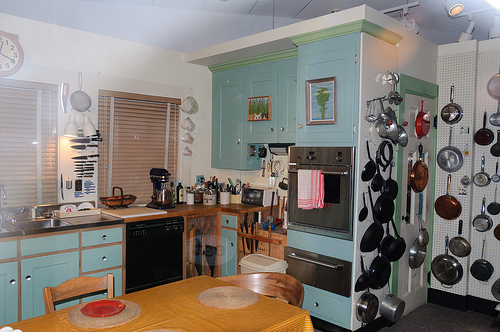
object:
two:
[410, 153, 462, 220]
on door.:
[400, 87, 434, 310]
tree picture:
[310, 82, 333, 121]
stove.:
[287, 146, 354, 236]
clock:
[1, 30, 26, 77]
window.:
[3, 77, 59, 205]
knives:
[70, 144, 100, 152]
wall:
[60, 78, 101, 206]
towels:
[296, 168, 324, 211]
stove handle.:
[289, 168, 348, 178]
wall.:
[8, 14, 212, 207]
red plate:
[80, 299, 127, 316]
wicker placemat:
[66, 300, 145, 326]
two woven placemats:
[70, 287, 267, 330]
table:
[0, 275, 313, 331]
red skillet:
[414, 98, 432, 140]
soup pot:
[380, 287, 406, 323]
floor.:
[378, 302, 499, 331]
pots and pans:
[359, 70, 499, 325]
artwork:
[247, 95, 272, 121]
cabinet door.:
[243, 72, 277, 142]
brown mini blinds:
[98, 92, 181, 196]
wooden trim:
[400, 74, 440, 100]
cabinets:
[275, 66, 297, 144]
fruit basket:
[100, 186, 137, 207]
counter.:
[101, 207, 265, 219]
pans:
[449, 220, 471, 258]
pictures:
[309, 80, 334, 122]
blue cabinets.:
[210, 68, 242, 171]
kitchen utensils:
[202, 188, 218, 206]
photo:
[3, 6, 498, 331]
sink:
[10, 217, 70, 232]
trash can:
[240, 254, 289, 274]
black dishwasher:
[124, 221, 184, 290]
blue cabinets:
[21, 251, 81, 319]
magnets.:
[84, 180, 94, 194]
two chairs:
[38, 271, 312, 315]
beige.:
[1, 33, 20, 42]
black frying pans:
[360, 143, 378, 182]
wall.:
[357, 34, 397, 328]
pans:
[434, 171, 461, 220]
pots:
[361, 140, 377, 182]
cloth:
[0, 274, 314, 332]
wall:
[365, 29, 484, 322]